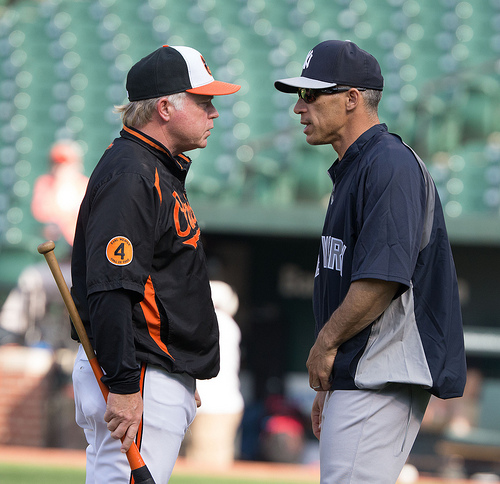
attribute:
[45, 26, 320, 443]
man — baseball player, light, wearing, holding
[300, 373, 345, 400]
ring — metal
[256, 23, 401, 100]
cap — black, grey, maroon, baseball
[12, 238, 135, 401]
bat — wooden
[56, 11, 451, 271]
men — baseball coach, talking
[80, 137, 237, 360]
jacket — black, orange, shortsleeved, blue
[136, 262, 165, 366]
stripe — orange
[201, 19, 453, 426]
person — wearing, holding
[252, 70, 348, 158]
glass — sun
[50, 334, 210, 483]
pant — white, stripped, grey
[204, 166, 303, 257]
seat — green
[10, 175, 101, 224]
shirt — red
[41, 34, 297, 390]
coach — baseball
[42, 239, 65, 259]
base — wooden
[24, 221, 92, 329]
handle — orange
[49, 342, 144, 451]
handl — holding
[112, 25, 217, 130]
hat — black, orange, white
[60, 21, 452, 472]
people — facing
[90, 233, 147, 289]
number — patch